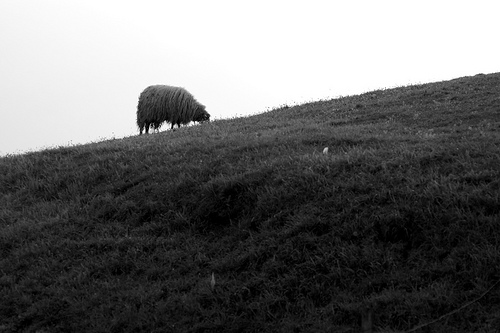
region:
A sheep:
[98, 82, 229, 133]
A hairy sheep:
[115, 81, 232, 155]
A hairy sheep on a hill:
[114, 69, 223, 145]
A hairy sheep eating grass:
[125, 75, 245, 140]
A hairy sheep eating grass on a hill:
[86, 58, 242, 176]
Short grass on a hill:
[215, 125, 338, 164]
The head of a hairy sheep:
[196, 95, 218, 131]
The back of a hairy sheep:
[139, 85, 192, 98]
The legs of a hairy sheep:
[136, 122, 189, 136]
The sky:
[242, 31, 315, 66]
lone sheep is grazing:
[129, 84, 211, 134]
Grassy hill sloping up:
[0, 71, 498, 331]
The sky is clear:
[0, 1, 499, 154]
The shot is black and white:
[0, 2, 499, 331]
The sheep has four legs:
[132, 85, 202, 128]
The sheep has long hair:
[135, 82, 197, 127]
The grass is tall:
[3, 146, 498, 331]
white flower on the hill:
[321, 144, 331, 175]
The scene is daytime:
[0, 0, 499, 330]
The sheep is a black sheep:
[135, 79, 215, 138]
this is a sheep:
[133, 87, 209, 128]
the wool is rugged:
[134, 86, 214, 126]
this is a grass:
[209, 126, 366, 176]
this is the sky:
[119, 22, 310, 88]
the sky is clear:
[9, 42, 133, 131]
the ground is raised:
[14, 113, 426, 226]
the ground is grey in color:
[100, 151, 440, 281]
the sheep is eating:
[116, 82, 228, 139]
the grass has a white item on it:
[312, 142, 342, 162]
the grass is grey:
[75, 158, 367, 246]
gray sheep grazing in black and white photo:
[126, 78, 225, 140]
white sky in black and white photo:
[3, 10, 164, 75]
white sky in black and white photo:
[135, 5, 296, 71]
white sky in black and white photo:
[247, 7, 447, 75]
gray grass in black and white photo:
[11, 159, 151, 267]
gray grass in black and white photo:
[171, 140, 370, 240]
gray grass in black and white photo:
[336, 101, 488, 242]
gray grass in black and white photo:
[296, 211, 467, 321]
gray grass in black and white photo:
[75, 203, 293, 325]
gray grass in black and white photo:
[13, 174, 172, 324]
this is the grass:
[182, 152, 361, 314]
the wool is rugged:
[141, 87, 178, 133]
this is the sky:
[33, 36, 96, 108]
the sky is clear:
[3, 7, 95, 122]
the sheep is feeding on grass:
[189, 104, 216, 126]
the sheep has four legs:
[137, 115, 189, 137]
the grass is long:
[213, 132, 337, 221]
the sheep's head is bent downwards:
[192, 102, 214, 128]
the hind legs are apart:
[137, 110, 154, 137]